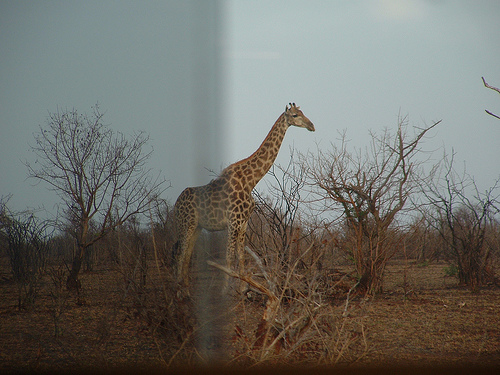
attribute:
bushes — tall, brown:
[320, 216, 402, 297]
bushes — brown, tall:
[2, 213, 56, 313]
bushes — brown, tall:
[201, 240, 363, 370]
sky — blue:
[245, 14, 493, 131]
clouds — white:
[0, 2, 498, 244]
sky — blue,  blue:
[3, 2, 498, 246]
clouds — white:
[277, 24, 484, 138]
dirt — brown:
[315, 297, 429, 305]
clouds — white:
[369, 30, 466, 87]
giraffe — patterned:
[165, 95, 318, 303]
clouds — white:
[45, 17, 187, 85]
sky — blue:
[171, 8, 449, 173]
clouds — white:
[301, 25, 474, 104]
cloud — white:
[201, 7, 496, 134]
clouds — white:
[23, 9, 496, 83]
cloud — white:
[240, 7, 498, 128]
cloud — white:
[354, 9, 446, 41]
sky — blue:
[4, 4, 496, 43]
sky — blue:
[9, 4, 495, 80]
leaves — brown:
[34, 335, 273, 357]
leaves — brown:
[343, 145, 390, 162]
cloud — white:
[346, 6, 452, 41]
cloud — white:
[224, 44, 308, 74]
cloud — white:
[275, 32, 493, 80]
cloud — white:
[316, 0, 464, 36]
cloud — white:
[336, 25, 397, 83]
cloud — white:
[358, 0, 434, 37]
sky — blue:
[9, 15, 495, 55]